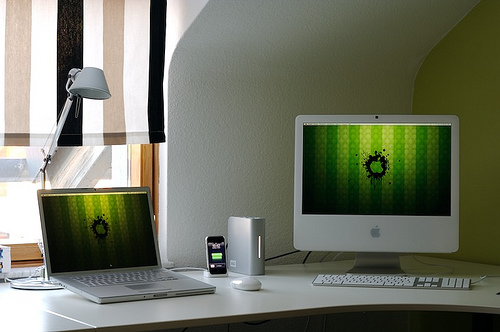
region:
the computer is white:
[49, 126, 201, 303]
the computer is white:
[46, 183, 151, 315]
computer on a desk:
[270, 108, 483, 273]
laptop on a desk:
[32, 180, 229, 321]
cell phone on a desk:
[193, 231, 233, 281]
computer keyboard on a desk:
[302, 270, 483, 293]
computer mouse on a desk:
[227, 269, 264, 296]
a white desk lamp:
[28, 54, 126, 196]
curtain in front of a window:
[0, 1, 176, 151]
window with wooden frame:
[0, 130, 165, 272]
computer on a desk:
[217, 210, 272, 285]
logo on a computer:
[367, 218, 387, 243]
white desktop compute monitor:
[294, 111, 459, 251]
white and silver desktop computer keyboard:
[312, 268, 474, 293]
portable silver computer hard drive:
[227, 213, 266, 275]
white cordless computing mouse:
[231, 271, 262, 290]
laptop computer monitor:
[35, 187, 162, 268]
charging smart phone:
[203, 232, 230, 278]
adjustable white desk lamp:
[29, 66, 112, 183]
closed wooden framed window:
[1, 142, 165, 273]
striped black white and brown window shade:
[6, 2, 163, 147]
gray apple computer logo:
[368, 222, 383, 239]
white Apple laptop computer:
[26, 186, 220, 312]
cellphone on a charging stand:
[191, 230, 238, 278]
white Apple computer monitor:
[275, 96, 478, 261]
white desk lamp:
[21, 68, 110, 196]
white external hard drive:
[225, 206, 277, 277]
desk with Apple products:
[28, 103, 488, 306]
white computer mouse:
[224, 263, 273, 301]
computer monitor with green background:
[294, 111, 473, 254]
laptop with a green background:
[28, 186, 227, 309]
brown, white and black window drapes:
[7, 5, 172, 146]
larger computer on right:
[296, 104, 472, 295]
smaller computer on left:
[31, 182, 213, 301]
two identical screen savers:
[40, 112, 463, 299]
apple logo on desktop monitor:
[366, 225, 385, 240]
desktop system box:
[224, 205, 269, 278]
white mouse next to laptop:
[226, 272, 265, 294]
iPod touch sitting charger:
[198, 229, 234, 281]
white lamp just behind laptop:
[16, 50, 100, 290]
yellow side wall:
[401, 1, 499, 268]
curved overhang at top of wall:
[162, 1, 499, 122]